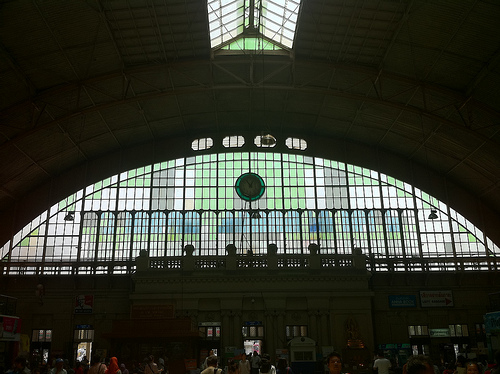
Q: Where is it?
A: This is at the station.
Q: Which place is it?
A: It is a station.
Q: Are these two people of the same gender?
A: No, they are both male and female.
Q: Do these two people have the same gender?
A: No, they are both male and female.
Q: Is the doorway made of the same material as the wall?
A: Yes, both the doorway and the wall are made of glass.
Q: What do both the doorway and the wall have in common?
A: The material, both the doorway and the wall are glass.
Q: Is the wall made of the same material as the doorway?
A: Yes, both the wall and the doorway are made of glass.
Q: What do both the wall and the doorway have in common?
A: The material, both the wall and the doorway are glass.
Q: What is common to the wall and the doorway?
A: The material, both the wall and the doorway are glass.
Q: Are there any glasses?
A: No, there are no glasses.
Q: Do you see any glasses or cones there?
A: No, there are no glasses or cones.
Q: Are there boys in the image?
A: No, there are no boys.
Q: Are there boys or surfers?
A: No, there are no boys or surfers.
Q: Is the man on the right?
A: Yes, the man is on the right of the image.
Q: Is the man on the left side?
A: No, the man is on the right of the image.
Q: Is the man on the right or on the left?
A: The man is on the right of the image.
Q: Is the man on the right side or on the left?
A: The man is on the right of the image.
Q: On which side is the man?
A: The man is on the right of the image.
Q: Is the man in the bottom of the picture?
A: Yes, the man is in the bottom of the image.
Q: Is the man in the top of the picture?
A: No, the man is in the bottom of the image.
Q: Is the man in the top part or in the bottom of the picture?
A: The man is in the bottom of the image.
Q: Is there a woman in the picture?
A: Yes, there is a woman.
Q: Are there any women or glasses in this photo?
A: Yes, there is a woman.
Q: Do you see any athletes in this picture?
A: No, there are no athletes.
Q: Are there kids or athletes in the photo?
A: No, there are no athletes or kids.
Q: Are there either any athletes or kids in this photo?
A: No, there are no athletes or kids.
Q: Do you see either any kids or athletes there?
A: No, there are no athletes or kids.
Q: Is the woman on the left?
A: Yes, the woman is on the left of the image.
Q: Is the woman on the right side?
A: No, the woman is on the left of the image.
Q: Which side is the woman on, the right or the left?
A: The woman is on the left of the image.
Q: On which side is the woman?
A: The woman is on the left of the image.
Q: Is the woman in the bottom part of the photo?
A: Yes, the woman is in the bottom of the image.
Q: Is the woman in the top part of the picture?
A: No, the woman is in the bottom of the image.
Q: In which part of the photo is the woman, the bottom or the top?
A: The woman is in the bottom of the image.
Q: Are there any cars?
A: No, there are no cars.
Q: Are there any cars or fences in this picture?
A: No, there are no cars or fences.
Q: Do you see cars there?
A: No, there are no cars.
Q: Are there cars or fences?
A: No, there are no cars or fences.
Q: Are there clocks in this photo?
A: Yes, there is a clock.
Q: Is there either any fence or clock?
A: Yes, there is a clock.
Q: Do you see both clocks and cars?
A: No, there is a clock but no cars.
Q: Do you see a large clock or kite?
A: Yes, there is a large clock.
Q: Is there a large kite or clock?
A: Yes, there is a large clock.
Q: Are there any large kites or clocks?
A: Yes, there is a large clock.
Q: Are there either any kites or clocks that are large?
A: Yes, the clock is large.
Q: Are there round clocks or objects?
A: Yes, there is a round clock.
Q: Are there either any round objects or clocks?
A: Yes, there is a round clock.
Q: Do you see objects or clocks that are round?
A: Yes, the clock is round.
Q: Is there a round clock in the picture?
A: Yes, there is a round clock.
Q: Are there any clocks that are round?
A: Yes, there is a clock that is round.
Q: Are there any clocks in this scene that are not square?
A: Yes, there is a round clock.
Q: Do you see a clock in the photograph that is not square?
A: Yes, there is a round clock.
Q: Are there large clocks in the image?
A: Yes, there is a large clock.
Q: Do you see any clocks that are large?
A: Yes, there is a clock that is large.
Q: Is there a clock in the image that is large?
A: Yes, there is a clock that is large.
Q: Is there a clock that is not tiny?
A: Yes, there is a large clock.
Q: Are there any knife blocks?
A: No, there are no knife blocks.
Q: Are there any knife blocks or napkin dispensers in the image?
A: No, there are no knife blocks or napkin dispensers.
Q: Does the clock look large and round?
A: Yes, the clock is large and round.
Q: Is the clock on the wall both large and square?
A: No, the clock is large but round.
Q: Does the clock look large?
A: Yes, the clock is large.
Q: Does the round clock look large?
A: Yes, the clock is large.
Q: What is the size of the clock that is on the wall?
A: The clock is large.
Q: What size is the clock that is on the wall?
A: The clock is large.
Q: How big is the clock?
A: The clock is large.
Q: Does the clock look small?
A: No, the clock is large.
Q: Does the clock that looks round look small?
A: No, the clock is large.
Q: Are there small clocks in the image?
A: No, there is a clock but it is large.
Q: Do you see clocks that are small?
A: No, there is a clock but it is large.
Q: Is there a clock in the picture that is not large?
A: No, there is a clock but it is large.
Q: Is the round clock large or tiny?
A: The clock is large.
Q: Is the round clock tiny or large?
A: The clock is large.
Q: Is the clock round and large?
A: Yes, the clock is round and large.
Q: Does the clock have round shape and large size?
A: Yes, the clock is round and large.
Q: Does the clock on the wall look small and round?
A: No, the clock is round but large.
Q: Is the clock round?
A: Yes, the clock is round.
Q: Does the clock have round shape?
A: Yes, the clock is round.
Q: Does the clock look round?
A: Yes, the clock is round.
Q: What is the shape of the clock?
A: The clock is round.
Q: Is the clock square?
A: No, the clock is round.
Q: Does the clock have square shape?
A: No, the clock is round.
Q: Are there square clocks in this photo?
A: No, there is a clock but it is round.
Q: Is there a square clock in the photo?
A: No, there is a clock but it is round.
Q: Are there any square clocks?
A: No, there is a clock but it is round.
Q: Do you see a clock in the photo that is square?
A: No, there is a clock but it is round.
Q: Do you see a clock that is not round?
A: No, there is a clock but it is round.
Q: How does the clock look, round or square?
A: The clock is round.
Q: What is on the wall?
A: The clock is on the wall.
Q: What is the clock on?
A: The clock is on the wall.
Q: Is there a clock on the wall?
A: Yes, there is a clock on the wall.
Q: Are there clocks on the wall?
A: Yes, there is a clock on the wall.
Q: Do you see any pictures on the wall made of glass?
A: No, there is a clock on the wall.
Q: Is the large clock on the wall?
A: Yes, the clock is on the wall.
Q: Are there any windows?
A: Yes, there is a window.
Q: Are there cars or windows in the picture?
A: Yes, there is a window.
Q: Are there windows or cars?
A: Yes, there is a window.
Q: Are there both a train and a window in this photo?
A: No, there is a window but no trains.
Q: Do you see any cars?
A: No, there are no cars.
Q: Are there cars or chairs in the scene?
A: No, there are no cars or chairs.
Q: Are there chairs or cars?
A: No, there are no cars or chairs.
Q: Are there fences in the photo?
A: No, there are no fences.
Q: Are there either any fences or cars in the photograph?
A: No, there are no fences or cars.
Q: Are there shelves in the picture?
A: No, there are no shelves.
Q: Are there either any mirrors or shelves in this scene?
A: No, there are no shelves or mirrors.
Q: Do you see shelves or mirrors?
A: No, there are no shelves or mirrors.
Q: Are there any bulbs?
A: No, there are no bulbs.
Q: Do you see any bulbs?
A: No, there are no bulbs.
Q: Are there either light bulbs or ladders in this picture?
A: No, there are no light bulbs or ladders.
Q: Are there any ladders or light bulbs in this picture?
A: No, there are no light bulbs or ladders.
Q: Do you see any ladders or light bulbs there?
A: No, there are no light bulbs or ladders.